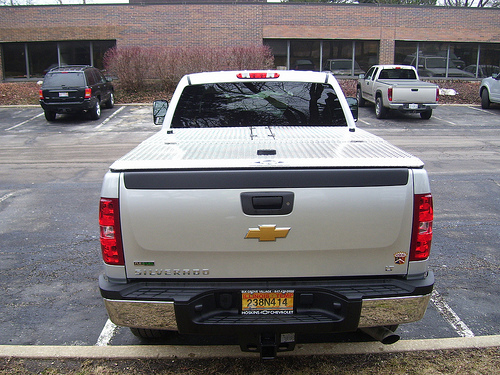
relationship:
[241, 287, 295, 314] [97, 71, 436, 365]
license plate on truck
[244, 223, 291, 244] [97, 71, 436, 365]
chevrolet logo on truck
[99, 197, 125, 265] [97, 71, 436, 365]
tail light on truck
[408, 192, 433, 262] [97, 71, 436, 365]
tail light on truck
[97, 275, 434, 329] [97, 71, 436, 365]
bumper on truck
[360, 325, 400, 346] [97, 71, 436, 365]
exhaust pipe on truck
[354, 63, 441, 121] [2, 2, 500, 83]
truck parked near building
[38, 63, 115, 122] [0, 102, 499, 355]
car in parking lot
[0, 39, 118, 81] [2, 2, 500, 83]
windows on building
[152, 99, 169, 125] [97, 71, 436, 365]
side mirror on truck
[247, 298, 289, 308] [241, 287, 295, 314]
number on license plate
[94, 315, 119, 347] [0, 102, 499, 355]
line on parking lot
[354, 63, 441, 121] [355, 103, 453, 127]
truck in parking spot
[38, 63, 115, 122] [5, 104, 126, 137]
car in parking spot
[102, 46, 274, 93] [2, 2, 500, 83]
bushes next to building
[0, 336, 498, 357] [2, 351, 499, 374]
curb next to grass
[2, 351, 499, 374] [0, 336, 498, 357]
grass next to curb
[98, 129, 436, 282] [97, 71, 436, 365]
flatbed on truck